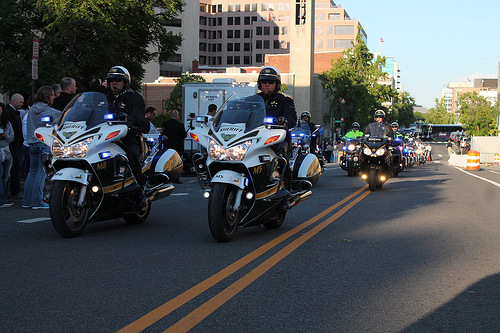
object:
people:
[21, 85, 63, 209]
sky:
[335, 0, 500, 80]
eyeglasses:
[260, 79, 278, 84]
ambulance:
[181, 77, 258, 173]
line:
[115, 183, 374, 333]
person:
[0, 93, 25, 199]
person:
[162, 110, 189, 185]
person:
[143, 106, 163, 156]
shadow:
[399, 271, 499, 333]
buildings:
[141, 0, 500, 138]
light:
[246, 192, 254, 200]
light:
[203, 191, 210, 198]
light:
[363, 147, 386, 157]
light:
[52, 136, 95, 159]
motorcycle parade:
[34, 65, 431, 243]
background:
[8, 5, 498, 205]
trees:
[392, 91, 434, 130]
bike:
[186, 92, 322, 242]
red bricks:
[313, 52, 344, 75]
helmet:
[256, 65, 281, 96]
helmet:
[105, 65, 131, 95]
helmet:
[373, 109, 385, 122]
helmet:
[300, 110, 311, 123]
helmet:
[390, 122, 399, 132]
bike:
[351, 122, 401, 191]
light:
[98, 151, 112, 160]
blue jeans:
[21, 141, 51, 206]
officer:
[390, 122, 404, 146]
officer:
[300, 111, 323, 169]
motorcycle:
[397, 141, 405, 172]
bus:
[419, 124, 467, 143]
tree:
[0, 0, 188, 103]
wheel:
[208, 182, 246, 241]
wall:
[470, 137, 499, 163]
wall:
[311, 0, 360, 79]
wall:
[454, 90, 498, 105]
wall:
[195, 0, 290, 77]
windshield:
[59, 91, 109, 130]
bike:
[34, 91, 184, 238]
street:
[0, 143, 500, 333]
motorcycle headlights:
[207, 139, 252, 162]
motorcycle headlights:
[51, 136, 93, 159]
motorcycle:
[339, 135, 365, 176]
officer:
[239, 65, 298, 210]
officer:
[364, 109, 395, 151]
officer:
[93, 65, 148, 208]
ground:
[6, 142, 492, 331]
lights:
[190, 132, 281, 162]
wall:
[268, 52, 345, 77]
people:
[51, 77, 78, 112]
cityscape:
[0, 0, 500, 333]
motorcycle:
[291, 124, 329, 176]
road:
[0, 158, 500, 333]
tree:
[451, 91, 500, 137]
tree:
[422, 97, 457, 125]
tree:
[316, 24, 407, 131]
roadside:
[0, 156, 490, 331]